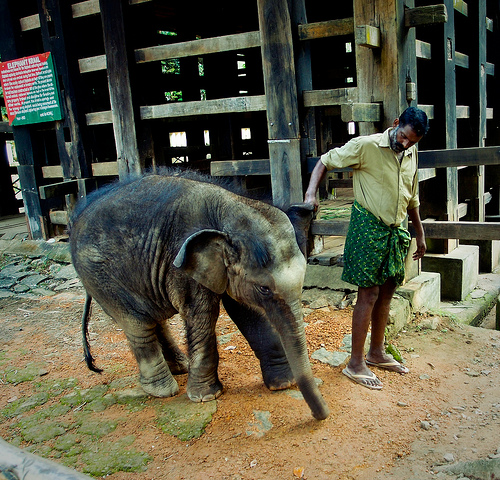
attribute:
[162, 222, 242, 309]
ear —   the left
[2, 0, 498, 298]
structure — wooden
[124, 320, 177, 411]
back leg — back  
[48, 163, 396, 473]
elephant —  with black hair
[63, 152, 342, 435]
elephant —  old